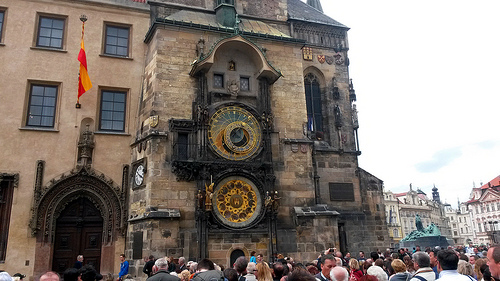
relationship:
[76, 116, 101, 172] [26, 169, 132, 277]
statue over arched doorway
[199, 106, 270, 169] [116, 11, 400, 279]
clock on building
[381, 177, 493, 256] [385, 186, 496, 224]
building on distance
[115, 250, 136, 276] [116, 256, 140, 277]
man wears blue shirt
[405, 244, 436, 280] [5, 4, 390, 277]
people front building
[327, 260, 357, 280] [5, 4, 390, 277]
people front building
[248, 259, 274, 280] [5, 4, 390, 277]
people front building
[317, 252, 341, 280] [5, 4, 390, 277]
people front building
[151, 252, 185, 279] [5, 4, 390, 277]
people front building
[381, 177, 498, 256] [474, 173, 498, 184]
building has roof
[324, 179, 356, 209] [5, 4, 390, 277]
plaque on building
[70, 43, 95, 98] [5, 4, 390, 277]
flags on building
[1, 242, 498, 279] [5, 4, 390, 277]
crowd front building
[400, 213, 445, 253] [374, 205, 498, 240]
statue in distance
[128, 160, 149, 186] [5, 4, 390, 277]
clock on building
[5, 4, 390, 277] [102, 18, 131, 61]
building has multi-pane window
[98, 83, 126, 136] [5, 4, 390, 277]
window on a building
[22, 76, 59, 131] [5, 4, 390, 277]
window on a building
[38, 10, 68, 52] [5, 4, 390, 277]
window on a building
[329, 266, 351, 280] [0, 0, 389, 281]
people in front of building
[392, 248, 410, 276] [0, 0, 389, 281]
person in front of building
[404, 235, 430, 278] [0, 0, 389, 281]
person in front of building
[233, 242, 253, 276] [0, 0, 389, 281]
person in front of building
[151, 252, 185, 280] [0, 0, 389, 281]
people in front of building